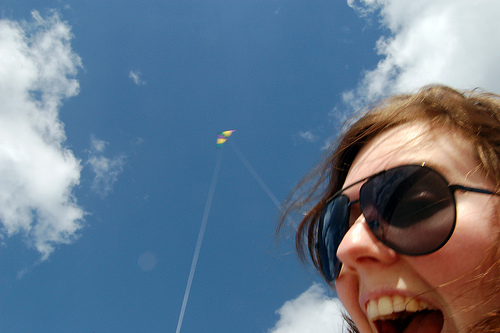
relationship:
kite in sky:
[215, 129, 238, 147] [85, 5, 329, 124]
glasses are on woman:
[318, 165, 457, 283] [273, 83, 499, 333]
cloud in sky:
[0, 2, 85, 266] [85, 5, 329, 124]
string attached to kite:
[153, 154, 227, 332] [215, 129, 238, 147]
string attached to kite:
[236, 147, 283, 215] [215, 129, 238, 147]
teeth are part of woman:
[368, 298, 434, 322] [273, 83, 499, 333]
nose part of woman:
[336, 216, 397, 275] [273, 83, 499, 333]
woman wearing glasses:
[273, 83, 499, 333] [318, 165, 457, 283]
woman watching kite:
[273, 83, 499, 333] [215, 129, 238, 147]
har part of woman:
[326, 80, 498, 179] [273, 83, 499, 333]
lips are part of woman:
[360, 287, 440, 308] [273, 83, 499, 333]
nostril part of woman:
[357, 251, 381, 265] [273, 83, 499, 333]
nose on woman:
[336, 216, 397, 275] [273, 83, 499, 333]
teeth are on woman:
[368, 298, 434, 322] [273, 83, 499, 333]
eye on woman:
[402, 189, 432, 215] [273, 83, 499, 333]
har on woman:
[326, 80, 498, 179] [273, 83, 499, 333]